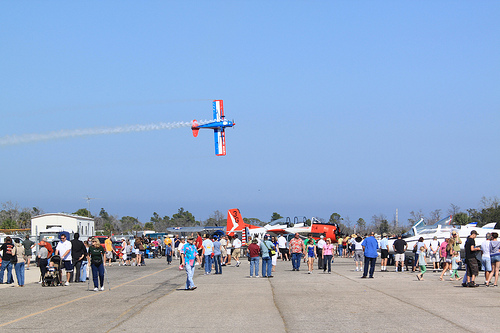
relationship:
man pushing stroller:
[54, 233, 71, 286] [42, 255, 64, 289]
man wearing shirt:
[54, 233, 71, 286] [55, 240, 73, 262]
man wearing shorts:
[54, 233, 71, 286] [59, 259, 75, 274]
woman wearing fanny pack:
[87, 237, 110, 286] [90, 257, 103, 266]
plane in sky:
[188, 98, 237, 158] [1, 1, 499, 155]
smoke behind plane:
[0, 119, 195, 144] [188, 98, 237, 158]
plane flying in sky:
[188, 98, 237, 158] [1, 1, 499, 155]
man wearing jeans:
[180, 236, 201, 291] [184, 264, 196, 291]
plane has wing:
[188, 98, 237, 158] [212, 97, 226, 122]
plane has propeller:
[188, 98, 237, 158] [230, 118, 237, 128]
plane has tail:
[188, 98, 237, 158] [190, 118, 201, 139]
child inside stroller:
[46, 259, 57, 276] [42, 255, 64, 289]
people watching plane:
[4, 229, 499, 288] [188, 98, 237, 158]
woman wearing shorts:
[306, 239, 319, 271] [303, 255, 315, 263]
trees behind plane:
[91, 209, 222, 231] [188, 98, 237, 158]